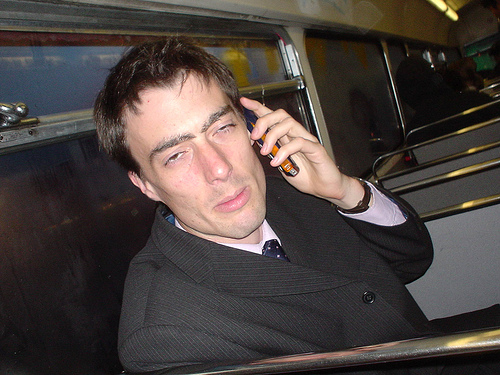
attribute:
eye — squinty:
[211, 122, 234, 135]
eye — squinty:
[161, 143, 191, 165]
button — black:
[361, 291, 374, 307]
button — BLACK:
[361, 287, 385, 317]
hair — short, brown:
[91, 33, 251, 175]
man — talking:
[88, 28, 440, 370]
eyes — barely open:
[166, 115, 246, 167]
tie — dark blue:
[259, 238, 291, 263]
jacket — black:
[154, 253, 410, 312]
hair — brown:
[91, 49, 239, 76]